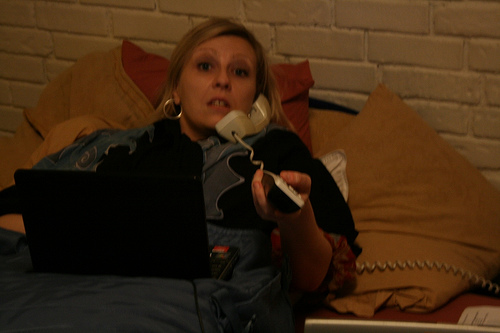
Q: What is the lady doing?
A: Talking on phone.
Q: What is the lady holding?
A: A remote.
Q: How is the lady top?
A: Blue.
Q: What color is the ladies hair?
A: Blonde.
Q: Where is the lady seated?
A: On the bed.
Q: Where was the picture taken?
A: In a bedroom.